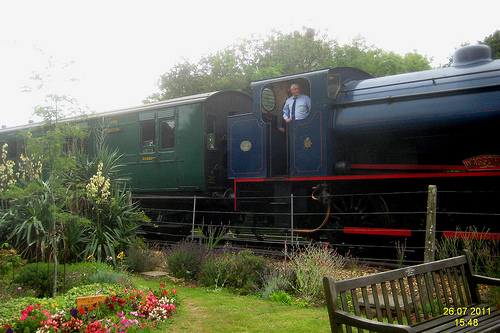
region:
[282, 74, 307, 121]
A man in the photo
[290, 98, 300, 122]
A black tie in the photo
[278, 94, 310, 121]
A blue shirt in the photo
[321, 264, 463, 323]
A bench in the photo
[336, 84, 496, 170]
A train in the photo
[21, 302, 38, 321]
Red flowers in the photo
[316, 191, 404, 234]
Train wheels in the photo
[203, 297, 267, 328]
Grass in the photo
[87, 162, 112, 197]
Yellow flowers in the photo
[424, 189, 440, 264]
A pole in the photo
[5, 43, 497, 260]
a train in front a garden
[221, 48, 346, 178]
a man stands on a train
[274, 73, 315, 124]
old man has gray hair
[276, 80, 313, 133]
man wears a blue shirt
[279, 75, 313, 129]
man has a tie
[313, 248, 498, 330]
a bench in a garden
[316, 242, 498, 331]
bench is made wood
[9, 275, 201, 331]
flowers in a garden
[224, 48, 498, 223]
car of train is blue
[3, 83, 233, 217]
car of train color green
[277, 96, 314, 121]
The shirt of a man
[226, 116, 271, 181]
A portion of a blue train.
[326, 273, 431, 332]
A portion of a bench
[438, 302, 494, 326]
The date of a picture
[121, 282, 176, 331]
A set of flowers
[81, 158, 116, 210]
A set of yellow buds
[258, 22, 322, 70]
A set of tree leaves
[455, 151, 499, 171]
A red logo with the word "waggon"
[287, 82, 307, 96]
The head of a man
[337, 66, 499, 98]
A railing on a blue train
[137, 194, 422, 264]
Wire fence bordering tracks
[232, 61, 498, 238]
Blue engine with red trim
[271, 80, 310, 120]
Trains engineer in first car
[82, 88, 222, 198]
Green passenger car following engine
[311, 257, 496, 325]
Brown wooden bench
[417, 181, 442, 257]
Weared brown fence posts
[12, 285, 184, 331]
Multicolored flower bed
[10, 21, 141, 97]
Overcast grey skies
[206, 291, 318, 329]
Green grass bordering tracks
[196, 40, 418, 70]
Leafy trees in background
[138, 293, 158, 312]
flowers in the grass.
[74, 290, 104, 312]
sign near the flowers.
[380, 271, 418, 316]
back of the bench.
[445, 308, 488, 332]
seat of the bench.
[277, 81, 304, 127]
man inside the train.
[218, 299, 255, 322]
grass on the ground.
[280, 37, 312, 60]
leaves on the tree.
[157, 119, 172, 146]
window on the train.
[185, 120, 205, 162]
green paint on train.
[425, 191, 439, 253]
fence post near train.